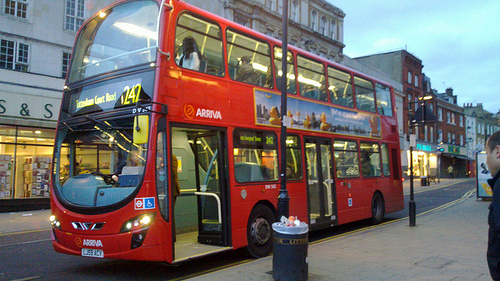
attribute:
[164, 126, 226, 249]
doorway — open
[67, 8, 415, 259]
bus — red, double decker, 2 levels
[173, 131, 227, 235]
door — opened, open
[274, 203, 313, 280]
trash can — black, grey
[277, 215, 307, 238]
trash bag — white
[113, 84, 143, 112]
247 — number, yellow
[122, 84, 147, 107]
number — green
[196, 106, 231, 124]
letters — white, yellow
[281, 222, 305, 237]
bag — white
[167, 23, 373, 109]
windows — passenger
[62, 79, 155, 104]
display — marquee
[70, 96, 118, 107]
lettering — green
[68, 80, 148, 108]
lights — yellow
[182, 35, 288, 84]
people — sitting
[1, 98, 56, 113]
letters — black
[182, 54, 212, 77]
shirt — white